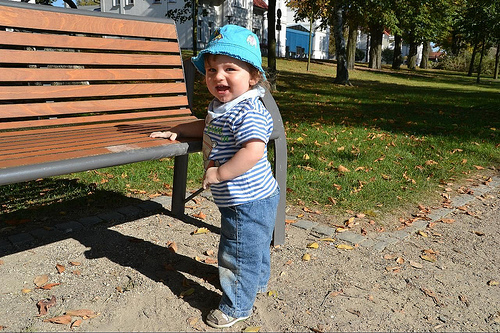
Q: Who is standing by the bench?
A: A child.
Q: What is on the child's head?
A: A hat.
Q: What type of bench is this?
A: Wooden and steel.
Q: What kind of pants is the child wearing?
A: Jeans.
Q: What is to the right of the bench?
A: Trees.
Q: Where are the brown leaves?
A: On the ground.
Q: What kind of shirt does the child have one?
A: Blue and white striped.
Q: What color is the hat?
A: Blue.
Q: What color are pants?
A: Blue.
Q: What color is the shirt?
A: Blue and white.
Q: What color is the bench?
A: Brown.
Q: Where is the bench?
A: Behind the boy.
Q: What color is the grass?
A: Green.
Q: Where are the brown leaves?
A: On the ground.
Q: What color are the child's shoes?
A: Gray.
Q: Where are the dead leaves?
A: In the grass.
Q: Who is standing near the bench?
A: A child.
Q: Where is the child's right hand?
A: On the bench.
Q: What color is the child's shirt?
A: Blue and white.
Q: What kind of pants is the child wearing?
A: Jeans.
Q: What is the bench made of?
A: Wood and steel.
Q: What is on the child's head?
A: A hat.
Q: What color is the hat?
A: Turquoise.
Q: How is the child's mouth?
A: Open.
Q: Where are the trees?
A: In the grass behind the bench.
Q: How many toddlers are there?
A: 1.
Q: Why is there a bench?
A: For sitting.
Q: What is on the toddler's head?
A: Hat.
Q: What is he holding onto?
A: The bench.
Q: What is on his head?
A: A blue hat.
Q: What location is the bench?
A: Park.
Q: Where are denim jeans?
A: On the tot.